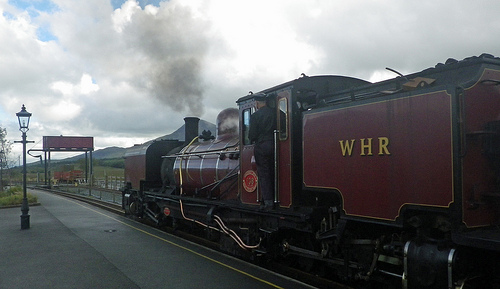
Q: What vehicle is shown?
A: Train.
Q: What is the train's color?
A: Red.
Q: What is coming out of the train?
A: Smoke.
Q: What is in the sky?
A: Clouds.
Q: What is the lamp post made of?
A: Metal.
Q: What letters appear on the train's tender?
A: WHR.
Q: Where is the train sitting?
A: On train tracks.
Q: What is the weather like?
A: Cloudy.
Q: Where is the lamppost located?
A: To the left of the train.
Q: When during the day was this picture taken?
A: Afternoon.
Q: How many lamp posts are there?
A: One.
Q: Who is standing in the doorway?
A: Conductor.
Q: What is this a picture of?
A: Train.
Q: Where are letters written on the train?
A: Side.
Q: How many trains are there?
A: One.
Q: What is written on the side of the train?
A: WHR.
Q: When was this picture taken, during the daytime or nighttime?
A: Daytime.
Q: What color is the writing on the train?
A: Yellow.